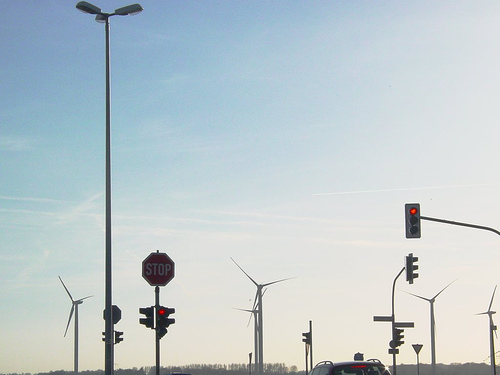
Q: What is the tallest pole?
A: The light pole.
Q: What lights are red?
A: The ones on top.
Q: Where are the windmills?
A: Behind the lights.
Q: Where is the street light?
A: Beside the stop sign.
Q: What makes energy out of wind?
A: The windmills.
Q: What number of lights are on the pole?
A: Three.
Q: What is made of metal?
A: Light pole.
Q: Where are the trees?
A: Behind the windmills.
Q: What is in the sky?
A: Clouds.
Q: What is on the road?
A: Wind mills.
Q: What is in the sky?
A: Clear blue sky.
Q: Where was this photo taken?
A: By a windmill park.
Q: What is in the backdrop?
A: Windmills and traffic lights.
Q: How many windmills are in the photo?
A: Five.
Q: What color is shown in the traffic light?
A: Red.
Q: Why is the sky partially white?
A: Because of the clouds.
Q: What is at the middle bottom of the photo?
A: A car.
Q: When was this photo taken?
A: Early morning.